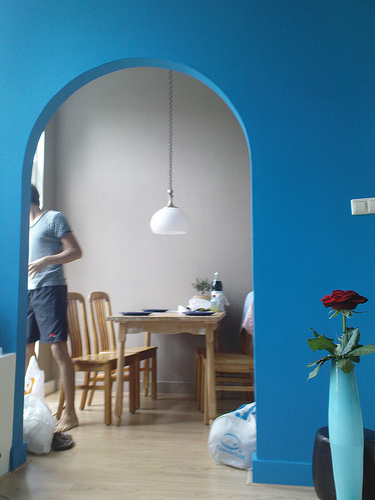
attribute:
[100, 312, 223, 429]
table — dining room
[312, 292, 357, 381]
rose — Red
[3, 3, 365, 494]
wall — blue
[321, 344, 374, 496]
vase — blue, smokey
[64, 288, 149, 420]
chairs — some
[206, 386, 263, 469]
bag — paper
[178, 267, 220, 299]
tree — Miniature, decorative 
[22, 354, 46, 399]
bag — white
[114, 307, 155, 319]
plate — blue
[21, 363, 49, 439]
bag — for Shopping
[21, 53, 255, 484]
doorway — arched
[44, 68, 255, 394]
wall — white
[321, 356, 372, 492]
vase — blue, for flower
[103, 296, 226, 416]
table — dining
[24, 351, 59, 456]
bag — plastic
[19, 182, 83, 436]
man — barefoot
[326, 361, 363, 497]
vase —  blue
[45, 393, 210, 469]
floor — kitchen's